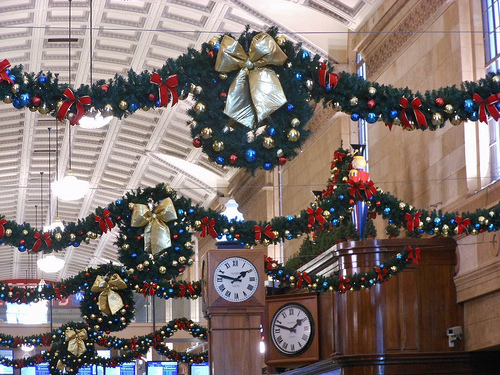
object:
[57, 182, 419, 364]
computers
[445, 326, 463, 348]
camera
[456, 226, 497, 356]
wall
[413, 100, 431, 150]
ground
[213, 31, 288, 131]
bow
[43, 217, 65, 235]
lights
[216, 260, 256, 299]
numbers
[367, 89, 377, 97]
balls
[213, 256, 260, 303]
clock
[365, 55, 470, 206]
walls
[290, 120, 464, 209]
wall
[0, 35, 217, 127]
wreath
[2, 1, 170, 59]
ceiling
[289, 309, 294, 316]
roman numerals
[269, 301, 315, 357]
clock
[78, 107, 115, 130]
light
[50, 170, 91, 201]
light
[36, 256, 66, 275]
light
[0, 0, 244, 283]
ceiling